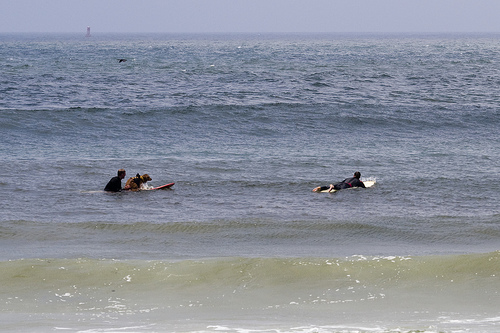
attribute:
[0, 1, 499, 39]
sky — cloudless, blue, clear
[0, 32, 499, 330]
water — blue, beautiful, ocean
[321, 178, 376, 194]
surfboard — white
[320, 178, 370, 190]
wetsuit — black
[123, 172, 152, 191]
dog — brown, surfing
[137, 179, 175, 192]
surfboard — red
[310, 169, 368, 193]
man — paddling, surfing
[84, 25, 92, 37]
floater — red, grey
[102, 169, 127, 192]
man — surfing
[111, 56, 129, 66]
bird — black, flying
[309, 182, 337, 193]
feet — bare